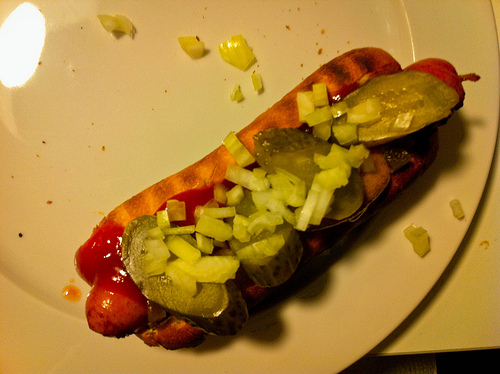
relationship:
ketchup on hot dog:
[72, 179, 236, 307] [85, 58, 480, 339]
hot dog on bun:
[85, 58, 480, 339] [95, 48, 437, 348]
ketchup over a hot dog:
[72, 179, 236, 307] [74, 47, 481, 349]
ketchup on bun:
[67, 219, 138, 296] [63, 39, 399, 249]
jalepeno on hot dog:
[250, 128, 365, 220] [74, 47, 481, 349]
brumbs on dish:
[6, 130, 113, 216] [0, 0, 499, 374]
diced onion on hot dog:
[147, 80, 393, 290] [74, 47, 481, 349]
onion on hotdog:
[226, 168, 334, 228] [87, 50, 479, 339]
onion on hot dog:
[294, 191, 317, 231] [74, 47, 481, 349]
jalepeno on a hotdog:
[333, 70, 459, 148] [87, 50, 479, 339]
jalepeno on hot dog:
[355, 79, 457, 131] [110, 44, 420, 343]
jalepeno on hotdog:
[286, 149, 363, 222] [415, 46, 456, 81]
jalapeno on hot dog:
[233, 213, 305, 293] [84, 55, 468, 333]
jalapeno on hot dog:
[113, 202, 264, 349] [49, 7, 489, 367]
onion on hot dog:
[181, 242, 238, 284] [55, 72, 468, 338]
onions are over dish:
[92, 8, 266, 98] [2, 0, 497, 370]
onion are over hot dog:
[196, 159, 363, 260] [82, 40, 435, 355]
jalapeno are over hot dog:
[122, 214, 249, 338] [74, 47, 481, 349]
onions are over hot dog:
[165, 88, 375, 287] [50, 32, 488, 344]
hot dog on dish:
[74, 47, 481, 349] [0, 0, 499, 374]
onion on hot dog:
[205, 208, 241, 232] [0, 3, 498, 372]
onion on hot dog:
[168, 232, 205, 264] [74, 47, 481, 349]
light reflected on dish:
[6, 14, 91, 84] [0, 0, 499, 374]